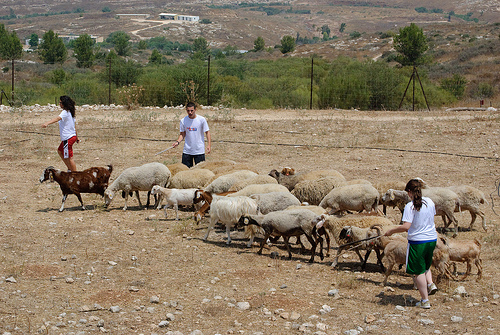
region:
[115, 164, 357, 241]
sheep standing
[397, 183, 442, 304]
a women is standing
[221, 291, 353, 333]
rocks on the ground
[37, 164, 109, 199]
a brown sheep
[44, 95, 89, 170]
a person standing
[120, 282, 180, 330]
small rocks on the ground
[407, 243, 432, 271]
green shorts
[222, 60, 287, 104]
the green bushes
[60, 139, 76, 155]
women wearing red shorts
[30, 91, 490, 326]
Young people herding goats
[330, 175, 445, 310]
Young girl herding goats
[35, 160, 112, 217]
Brown goat with white spots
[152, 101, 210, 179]
Young man herding goats with whip or stick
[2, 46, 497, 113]
Fence enclosing farmland and pasture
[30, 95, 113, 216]
Young woman leading goat herd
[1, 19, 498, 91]
Hilly landscape above town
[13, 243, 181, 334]
Dry land with rocks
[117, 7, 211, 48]
Large white building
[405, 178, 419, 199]
Person has brown hair.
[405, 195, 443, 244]
Person wearing white shirt.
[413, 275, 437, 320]
Person wearing tennis shoes.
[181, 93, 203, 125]
Person has dark hair.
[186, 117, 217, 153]
Person wearing white shirt.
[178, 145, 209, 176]
Person wearing dark pants.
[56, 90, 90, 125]
Person has dark hair.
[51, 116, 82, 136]
Person wearing white shirt.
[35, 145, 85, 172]
Person wearing red shorts.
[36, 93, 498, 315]
people herding goats and sheep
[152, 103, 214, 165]
man in a white t-shirt and a stick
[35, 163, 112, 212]
brown goat walking in the dirt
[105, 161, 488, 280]
white sheep walking in the dirt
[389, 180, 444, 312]
female with green shorts and white t-shirt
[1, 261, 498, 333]
rocks laying on the ground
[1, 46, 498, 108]
metal fencing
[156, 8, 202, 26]
house on the side of the hill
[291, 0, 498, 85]
hill side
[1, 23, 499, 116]
green brush and trees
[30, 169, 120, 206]
A brown with white goat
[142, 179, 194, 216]
A small white goat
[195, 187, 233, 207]
A brown with white goat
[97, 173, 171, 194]
A white sheep on a sandy field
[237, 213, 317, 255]
A white sheep on a sandy field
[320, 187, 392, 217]
A white sheep on a sandy field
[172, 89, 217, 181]
A man herding sheep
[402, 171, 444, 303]
A woman herding sheep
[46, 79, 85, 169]
A woman herding sheep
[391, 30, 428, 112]
A green tall tree